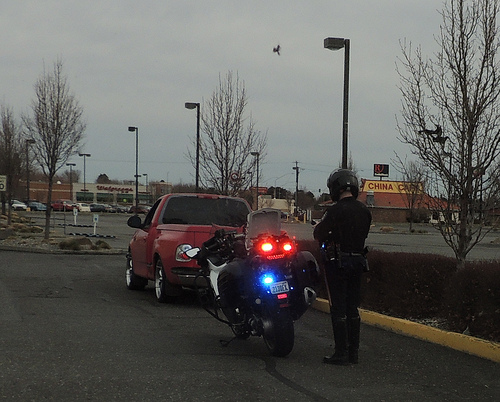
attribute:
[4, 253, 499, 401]
street — calm, black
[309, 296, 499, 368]
curb — yellow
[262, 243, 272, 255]
light — red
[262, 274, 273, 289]
light — blue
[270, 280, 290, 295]
license plate — white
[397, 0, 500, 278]
tree — branching, dry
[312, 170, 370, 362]
police officer — standing, writing, ticketing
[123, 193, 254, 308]
truck — red, parked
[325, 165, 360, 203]
helmet — black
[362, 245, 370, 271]
gun — holstered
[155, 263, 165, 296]
rim — chrome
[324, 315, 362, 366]
boots — black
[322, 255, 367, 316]
pants — black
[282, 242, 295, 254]
light — red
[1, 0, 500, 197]
sky — gray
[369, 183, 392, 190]
china — distant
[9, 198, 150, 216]
cars — distant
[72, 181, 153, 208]
walgreens — distant, drugstore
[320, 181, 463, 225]
restaurant — chinese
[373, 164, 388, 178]
sign — radioshack